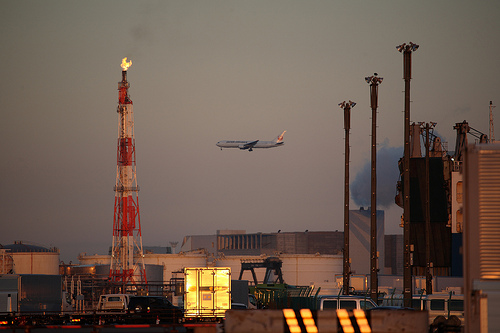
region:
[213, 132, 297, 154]
A plane in the air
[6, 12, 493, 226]
The sky is foggy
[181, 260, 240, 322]
The back of a truck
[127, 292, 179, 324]
A van looking vehicle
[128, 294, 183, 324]
The van is a black color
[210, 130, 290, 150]
The plane is long and white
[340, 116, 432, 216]
pollution is coming from a building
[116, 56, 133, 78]
Fire coming from a white and red object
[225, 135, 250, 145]
windows are on the plane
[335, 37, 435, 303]
Tall brown poles outside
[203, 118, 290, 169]
plane flying in sky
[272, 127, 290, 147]
small tail fin of plane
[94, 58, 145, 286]
tall white and red tower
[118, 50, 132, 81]
red flame at tip of tower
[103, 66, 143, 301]
tall metal tower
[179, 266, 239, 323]
back of a semi truck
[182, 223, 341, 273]
large white building in background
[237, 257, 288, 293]
green metal structure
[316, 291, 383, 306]
roof of a car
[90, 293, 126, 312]
back part of a truck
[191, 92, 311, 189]
plane in the air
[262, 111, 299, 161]
tail of the plane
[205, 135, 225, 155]
nose of the plane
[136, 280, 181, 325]
car on the ground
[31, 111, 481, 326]
many things in the photo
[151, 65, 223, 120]
sky above the plane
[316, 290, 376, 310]
windows on the car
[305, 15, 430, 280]
three poles in the photo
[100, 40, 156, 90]
top part of the item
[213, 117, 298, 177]
plane above the cars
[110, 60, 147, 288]
A red and white metal tower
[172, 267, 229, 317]
A large white truck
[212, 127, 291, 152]
A airplane in the sky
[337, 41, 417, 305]
Three tall metal poles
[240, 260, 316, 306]
An industrial grade machine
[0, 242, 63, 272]
A concrete silo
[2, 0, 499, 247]
A darkened gray sky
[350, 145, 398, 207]
A cloud of smoke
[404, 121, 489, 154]
Heavy mechanical machinery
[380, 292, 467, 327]
A row of several parked cars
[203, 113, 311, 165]
this is a plane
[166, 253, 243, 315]
the rear of a truck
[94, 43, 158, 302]
this is a mast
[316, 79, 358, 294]
this is a mast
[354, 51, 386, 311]
this is a mast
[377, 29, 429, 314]
this is a mast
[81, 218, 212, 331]
this is a building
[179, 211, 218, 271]
this is a building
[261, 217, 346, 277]
this is a building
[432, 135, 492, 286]
this is a building